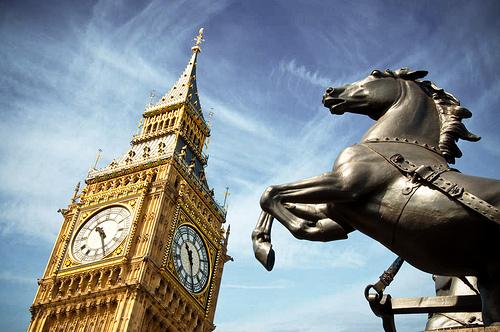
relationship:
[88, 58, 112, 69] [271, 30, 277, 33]
clouds in sky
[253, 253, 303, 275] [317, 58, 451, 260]
hooves of statue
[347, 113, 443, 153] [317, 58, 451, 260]
bridle of statue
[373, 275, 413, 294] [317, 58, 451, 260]
rope of statue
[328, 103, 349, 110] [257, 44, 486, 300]
mouth of horse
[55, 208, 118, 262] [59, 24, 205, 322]
clock on tower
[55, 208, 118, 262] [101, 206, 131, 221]
clock on white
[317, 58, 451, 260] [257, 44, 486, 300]
statue of horse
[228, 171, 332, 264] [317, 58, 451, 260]
legs of statue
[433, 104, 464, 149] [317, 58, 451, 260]
mane of statue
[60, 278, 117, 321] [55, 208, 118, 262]
arches under clock